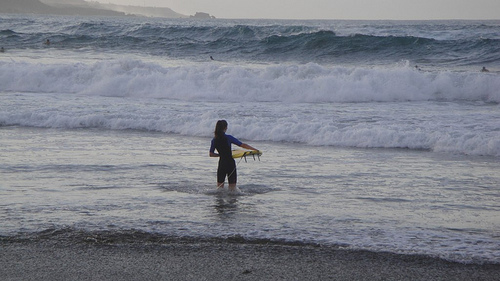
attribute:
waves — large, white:
[288, 71, 360, 98]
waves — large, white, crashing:
[17, 16, 471, 115]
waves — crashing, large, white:
[53, 16, 492, 86]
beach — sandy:
[35, 243, 344, 279]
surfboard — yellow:
[230, 138, 264, 173]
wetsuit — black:
[212, 135, 246, 177]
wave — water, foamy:
[40, 35, 317, 103]